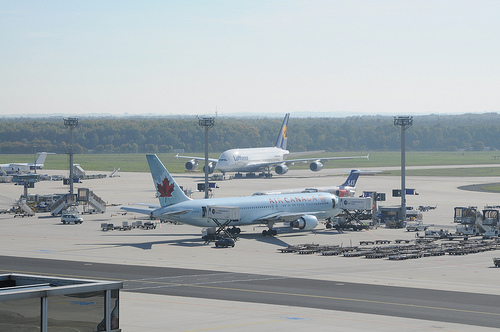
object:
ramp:
[203, 218, 237, 244]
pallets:
[277, 239, 500, 260]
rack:
[389, 254, 419, 260]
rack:
[342, 251, 362, 256]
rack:
[277, 245, 298, 253]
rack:
[448, 242, 470, 255]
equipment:
[298, 249, 318, 253]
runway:
[0, 164, 500, 332]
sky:
[0, 0, 500, 119]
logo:
[269, 194, 327, 204]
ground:
[0, 151, 500, 292]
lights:
[393, 116, 413, 130]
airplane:
[120, 154, 344, 237]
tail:
[146, 154, 191, 207]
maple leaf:
[157, 176, 176, 203]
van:
[61, 210, 84, 224]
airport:
[0, 0, 500, 332]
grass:
[328, 166, 500, 176]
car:
[215, 237, 236, 247]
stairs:
[87, 191, 106, 213]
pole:
[401, 125, 406, 228]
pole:
[205, 126, 209, 199]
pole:
[69, 126, 72, 194]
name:
[269, 195, 328, 205]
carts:
[144, 221, 158, 229]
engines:
[275, 164, 290, 174]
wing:
[244, 154, 369, 174]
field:
[0, 151, 500, 173]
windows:
[242, 206, 274, 210]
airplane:
[174, 113, 369, 177]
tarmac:
[0, 254, 500, 331]